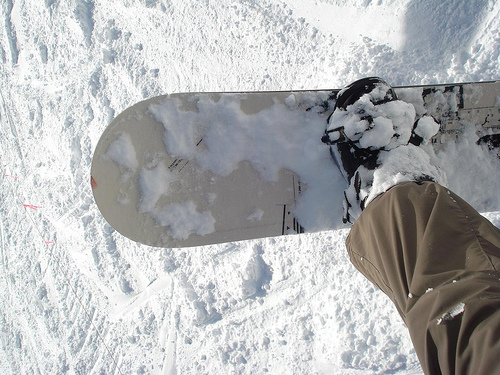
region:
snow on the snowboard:
[91, 76, 499, 250]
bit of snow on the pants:
[430, 302, 472, 322]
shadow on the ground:
[389, 6, 488, 81]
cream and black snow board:
[89, 78, 497, 263]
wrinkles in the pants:
[354, 188, 458, 306]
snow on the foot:
[325, 86, 452, 215]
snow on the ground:
[3, 2, 499, 374]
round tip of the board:
[78, 106, 185, 266]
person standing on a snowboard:
[69, 51, 499, 373]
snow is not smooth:
[2, 1, 464, 373]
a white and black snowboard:
[87, 79, 499, 249]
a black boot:
[330, 76, 442, 216]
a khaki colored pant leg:
[350, 180, 497, 370]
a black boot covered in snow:
[325, 76, 421, 196]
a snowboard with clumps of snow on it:
[87, 76, 495, 251]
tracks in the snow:
[4, 207, 94, 373]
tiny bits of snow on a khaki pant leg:
[402, 277, 470, 299]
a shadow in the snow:
[397, 0, 474, 70]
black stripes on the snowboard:
[289, 163, 309, 236]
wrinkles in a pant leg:
[395, 203, 478, 371]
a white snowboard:
[76, 77, 497, 267]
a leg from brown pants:
[345, 175, 470, 370]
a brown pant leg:
[350, 176, 491, 371]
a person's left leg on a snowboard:
[340, 90, 496, 365]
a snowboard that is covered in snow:
[96, 87, 496, 242]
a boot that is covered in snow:
[331, 70, 428, 242]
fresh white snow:
[0, 264, 340, 366]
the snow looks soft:
[1, 260, 338, 365]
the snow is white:
[16, 260, 376, 368]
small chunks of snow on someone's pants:
[395, 280, 480, 326]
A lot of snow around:
[33, 2, 459, 370]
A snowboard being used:
[88, 81, 495, 247]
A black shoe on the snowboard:
[285, 75, 440, 206]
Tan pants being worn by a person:
[335, 187, 495, 364]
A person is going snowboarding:
[81, 80, 491, 370]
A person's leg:
[360, 187, 490, 367]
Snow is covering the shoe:
[330, 65, 422, 190]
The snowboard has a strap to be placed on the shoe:
[320, 120, 440, 140]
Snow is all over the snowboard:
[120, 100, 495, 210]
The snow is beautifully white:
[19, 21, 491, 371]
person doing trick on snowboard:
[127, 76, 489, 244]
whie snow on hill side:
[16, 7, 101, 77]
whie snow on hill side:
[13, 73, 100, 153]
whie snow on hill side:
[16, 141, 74, 229]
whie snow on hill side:
[10, 234, 107, 341]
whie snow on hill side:
[113, 257, 225, 368]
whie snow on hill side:
[203, 253, 298, 341]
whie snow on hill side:
[289, 244, 340, 352]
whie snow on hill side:
[60, 16, 182, 76]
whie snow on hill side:
[201, 9, 326, 56]